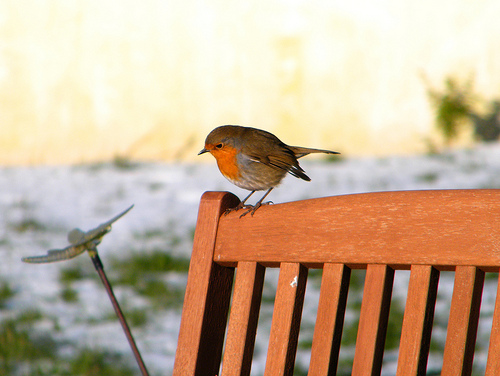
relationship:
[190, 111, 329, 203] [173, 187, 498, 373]
bird sitting on bench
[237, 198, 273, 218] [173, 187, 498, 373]
foot on a bench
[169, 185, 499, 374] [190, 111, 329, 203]
wooden bench with a bird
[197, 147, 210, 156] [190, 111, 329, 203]
beak on a bird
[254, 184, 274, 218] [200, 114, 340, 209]
foot of a bird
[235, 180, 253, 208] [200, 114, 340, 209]
foot of a bird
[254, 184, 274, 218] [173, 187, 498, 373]
foot on a bench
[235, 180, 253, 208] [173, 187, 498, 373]
foot on a bench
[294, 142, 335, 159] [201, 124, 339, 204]
tail of a bird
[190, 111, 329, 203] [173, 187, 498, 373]
bird perched on a bench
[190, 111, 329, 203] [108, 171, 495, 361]
bird perched on a bench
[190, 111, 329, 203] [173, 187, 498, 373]
bird on a bench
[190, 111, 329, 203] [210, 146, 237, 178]
bird has a chest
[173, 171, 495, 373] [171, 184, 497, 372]
bench made of wood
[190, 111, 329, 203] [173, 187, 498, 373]
bird perched on bench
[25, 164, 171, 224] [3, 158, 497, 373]
snow on ground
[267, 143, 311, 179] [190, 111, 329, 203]
feathers on bird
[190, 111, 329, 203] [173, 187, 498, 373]
bird on bench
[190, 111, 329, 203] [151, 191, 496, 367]
bird on chair back